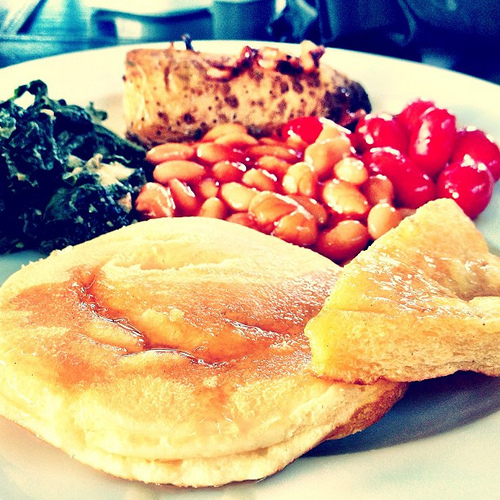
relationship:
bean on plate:
[150, 124, 396, 237] [0, 40, 500, 500]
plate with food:
[5, 453, 489, 495] [3, 32, 498, 488]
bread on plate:
[303, 196, 499, 382] [0, 40, 500, 500]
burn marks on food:
[276, 57, 306, 82] [120, 39, 372, 149]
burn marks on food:
[339, 78, 375, 110] [120, 39, 372, 149]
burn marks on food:
[213, 46, 257, 78] [120, 39, 372, 149]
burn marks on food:
[217, 94, 241, 111] [120, 39, 372, 149]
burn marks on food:
[180, 113, 207, 140] [120, 39, 372, 149]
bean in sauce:
[367, 202, 395, 249] [138, 110, 409, 260]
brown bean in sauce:
[246, 187, 316, 245] [130, 96, 497, 265]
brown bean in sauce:
[153, 130, 393, 245] [130, 96, 497, 265]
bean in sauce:
[150, 157, 206, 183] [124, 118, 405, 260]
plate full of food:
[0, 40, 500, 500] [3, 32, 498, 488]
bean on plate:
[150, 124, 396, 237] [0, 40, 450, 496]